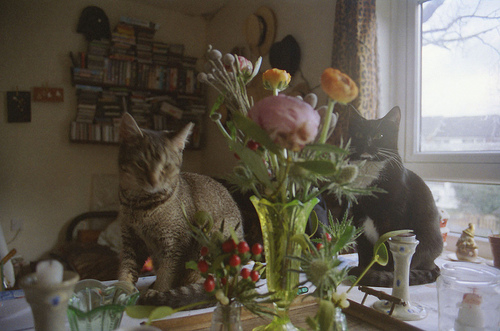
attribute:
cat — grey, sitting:
[110, 114, 246, 307]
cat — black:
[326, 100, 440, 282]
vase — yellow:
[245, 196, 314, 330]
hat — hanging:
[268, 36, 300, 81]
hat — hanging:
[246, 2, 276, 55]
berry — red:
[202, 279, 220, 295]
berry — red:
[248, 267, 261, 283]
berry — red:
[251, 239, 262, 256]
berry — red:
[229, 255, 239, 271]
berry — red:
[198, 261, 208, 274]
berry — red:
[222, 238, 237, 255]